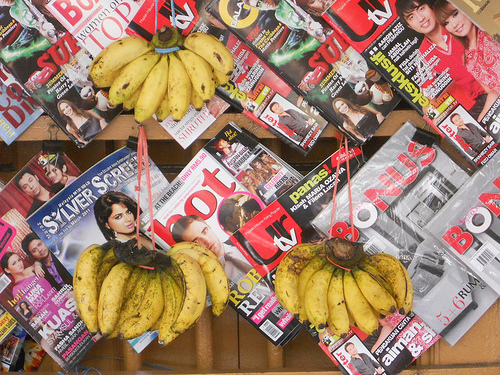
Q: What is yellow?
A: Bananas.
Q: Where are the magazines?
A: Hanging behind the bananas.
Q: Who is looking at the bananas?
A: The photographer.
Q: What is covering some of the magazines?
A: Plastic.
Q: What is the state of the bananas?
A: Starting to turn overripe.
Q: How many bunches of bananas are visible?
A: Three.